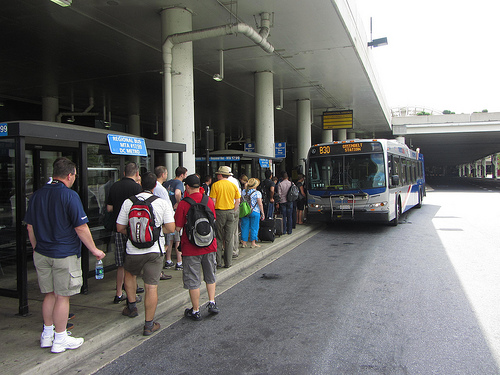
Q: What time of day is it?
A: Day time.